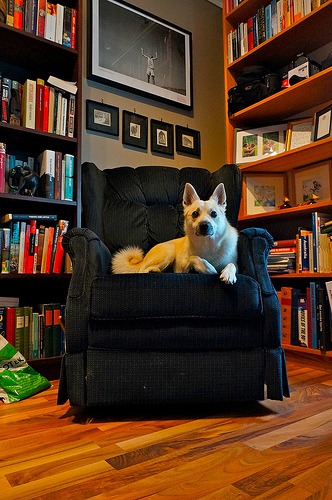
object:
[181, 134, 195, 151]
picture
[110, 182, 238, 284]
dog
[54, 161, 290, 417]
chair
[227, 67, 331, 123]
shelf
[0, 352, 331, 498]
floor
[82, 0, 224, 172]
wall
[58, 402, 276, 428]
shadow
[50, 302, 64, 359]
books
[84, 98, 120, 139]
frame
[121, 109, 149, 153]
frame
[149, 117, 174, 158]
frame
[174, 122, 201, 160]
frame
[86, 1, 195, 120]
frame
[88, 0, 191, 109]
picture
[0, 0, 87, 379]
book shelf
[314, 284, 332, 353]
books